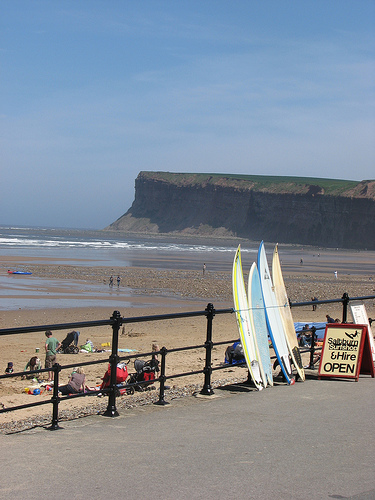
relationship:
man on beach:
[36, 325, 66, 372] [4, 241, 373, 419]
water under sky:
[3, 221, 276, 279] [1, 8, 374, 222]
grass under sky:
[164, 167, 357, 190] [1, 8, 374, 222]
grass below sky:
[164, 167, 357, 190] [1, 8, 374, 222]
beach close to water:
[4, 241, 373, 419] [3, 221, 276, 279]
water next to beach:
[3, 221, 276, 279] [4, 241, 373, 419]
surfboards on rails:
[230, 235, 312, 401] [12, 292, 374, 430]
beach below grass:
[4, 241, 373, 419] [164, 167, 357, 190]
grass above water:
[164, 167, 357, 190] [3, 221, 276, 279]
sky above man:
[1, 8, 374, 222] [36, 325, 66, 372]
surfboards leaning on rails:
[230, 235, 312, 401] [12, 292, 374, 430]